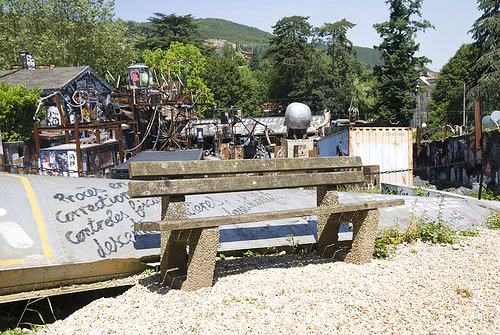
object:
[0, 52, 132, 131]
house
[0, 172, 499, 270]
paint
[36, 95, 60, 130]
wall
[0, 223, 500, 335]
ground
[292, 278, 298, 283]
gravel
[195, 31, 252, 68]
buildings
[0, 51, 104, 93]
roof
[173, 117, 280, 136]
roof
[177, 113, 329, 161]
house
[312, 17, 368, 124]
tree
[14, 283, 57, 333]
tall grass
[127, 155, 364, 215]
backrest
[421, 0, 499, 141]
tree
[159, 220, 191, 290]
legs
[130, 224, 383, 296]
shadow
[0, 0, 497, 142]
trees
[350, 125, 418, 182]
wall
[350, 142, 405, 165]
paint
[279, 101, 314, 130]
ball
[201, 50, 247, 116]
tree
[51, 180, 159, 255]
writing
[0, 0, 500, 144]
tree lines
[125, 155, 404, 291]
bench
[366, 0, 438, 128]
tree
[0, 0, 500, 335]
background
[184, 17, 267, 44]
mountain line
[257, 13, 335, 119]
tree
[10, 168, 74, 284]
line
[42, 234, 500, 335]
pebbles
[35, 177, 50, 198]
gray paint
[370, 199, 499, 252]
weeds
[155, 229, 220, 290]
leg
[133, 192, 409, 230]
seat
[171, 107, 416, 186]
building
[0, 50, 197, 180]
building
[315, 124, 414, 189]
container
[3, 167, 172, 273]
sidewalk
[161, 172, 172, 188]
bolts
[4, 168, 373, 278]
wall